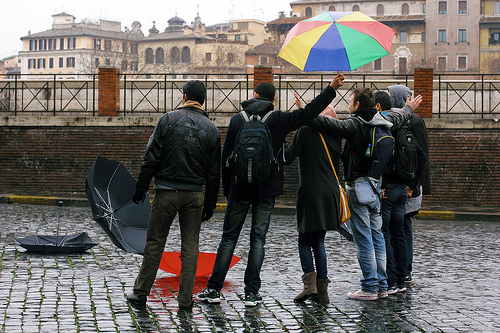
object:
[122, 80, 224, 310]
man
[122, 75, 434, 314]
group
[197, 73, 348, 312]
man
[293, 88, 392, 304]
man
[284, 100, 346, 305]
woman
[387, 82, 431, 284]
man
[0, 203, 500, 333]
road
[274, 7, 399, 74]
umbrella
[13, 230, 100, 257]
umbrella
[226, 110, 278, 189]
backpack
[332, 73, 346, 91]
hand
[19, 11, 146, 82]
building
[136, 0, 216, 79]
building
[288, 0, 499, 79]
building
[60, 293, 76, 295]
cobblestone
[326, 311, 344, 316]
cobblestone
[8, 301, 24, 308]
cobblestone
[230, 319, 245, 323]
cobblestone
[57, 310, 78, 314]
cobblestone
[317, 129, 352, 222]
sling bag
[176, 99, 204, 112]
scarf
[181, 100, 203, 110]
neck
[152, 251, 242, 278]
umbrella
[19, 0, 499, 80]
row of buildings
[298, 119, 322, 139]
shoulder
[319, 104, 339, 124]
head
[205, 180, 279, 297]
jeans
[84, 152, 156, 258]
umbrella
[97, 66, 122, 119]
fence support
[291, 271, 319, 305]
boot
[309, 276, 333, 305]
boot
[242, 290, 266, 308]
shoe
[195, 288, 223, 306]
shoe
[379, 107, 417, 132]
arm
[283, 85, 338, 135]
arm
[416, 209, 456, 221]
paint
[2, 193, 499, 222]
curb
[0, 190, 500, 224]
sidewalk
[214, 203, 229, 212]
paint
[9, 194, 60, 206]
paint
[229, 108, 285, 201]
back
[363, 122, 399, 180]
backpack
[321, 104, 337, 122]
hat